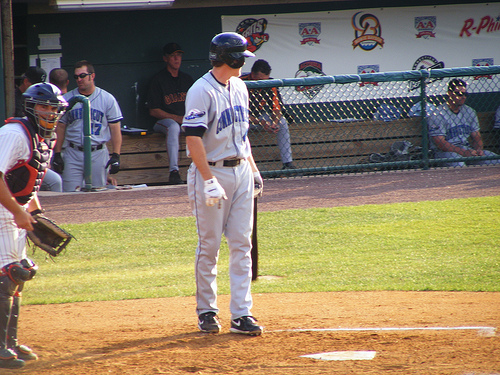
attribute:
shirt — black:
[140, 66, 192, 131]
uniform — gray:
[181, 66, 262, 318]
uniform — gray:
[423, 100, 495, 168]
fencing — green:
[314, 70, 452, 206]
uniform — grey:
[176, 75, 279, 327]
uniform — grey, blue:
[168, 85, 304, 335]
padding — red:
[6, 255, 42, 295]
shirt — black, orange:
[252, 83, 290, 133]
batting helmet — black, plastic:
[15, 77, 71, 137]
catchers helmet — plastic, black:
[21, 77, 70, 134]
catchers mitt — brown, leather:
[31, 199, 81, 264]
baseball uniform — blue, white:
[178, 72, 299, 319]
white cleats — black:
[182, 311, 266, 356]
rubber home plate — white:
[20, 33, 243, 179]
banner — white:
[228, 13, 498, 105]